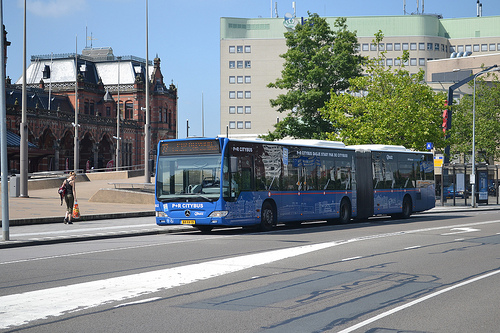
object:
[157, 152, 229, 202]
window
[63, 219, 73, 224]
high heels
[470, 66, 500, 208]
post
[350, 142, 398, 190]
ground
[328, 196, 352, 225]
tire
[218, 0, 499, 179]
building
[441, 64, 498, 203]
lamppost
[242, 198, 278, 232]
wheel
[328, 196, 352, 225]
wheel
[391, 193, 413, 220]
wheel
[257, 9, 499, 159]
trees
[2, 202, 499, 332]
street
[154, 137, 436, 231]
blue bus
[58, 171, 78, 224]
person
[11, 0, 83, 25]
cloud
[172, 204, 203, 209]
letters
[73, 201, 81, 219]
bag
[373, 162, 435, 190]
window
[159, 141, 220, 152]
sign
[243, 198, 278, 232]
tire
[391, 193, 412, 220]
tire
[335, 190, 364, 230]
tire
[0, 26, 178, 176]
building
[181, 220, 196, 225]
licence plate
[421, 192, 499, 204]
sidewalk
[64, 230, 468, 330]
road